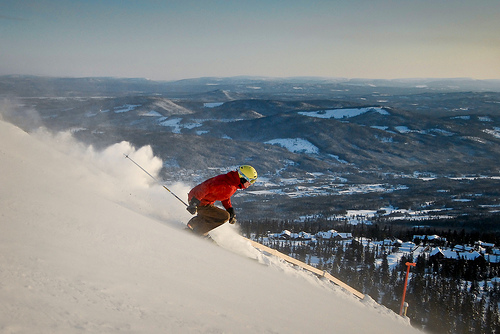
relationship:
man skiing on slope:
[189, 161, 257, 236] [17, 213, 417, 332]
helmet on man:
[237, 164, 259, 180] [181, 159, 257, 248]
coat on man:
[188, 170, 246, 206] [181, 159, 257, 248]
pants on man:
[189, 202, 230, 239] [185, 161, 259, 239]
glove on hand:
[182, 191, 199, 215] [187, 198, 196, 212]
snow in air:
[0, 114, 436, 330] [2, 3, 496, 85]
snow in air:
[297, 107, 390, 119] [2, 3, 496, 85]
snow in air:
[266, 134, 319, 155] [2, 3, 496, 85]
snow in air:
[327, 204, 458, 224] [2, 3, 496, 85]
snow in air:
[367, 122, 392, 131] [2, 3, 496, 85]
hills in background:
[0, 75, 497, 178] [5, 2, 494, 169]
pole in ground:
[393, 256, 418, 316] [0, 118, 425, 331]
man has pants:
[187, 165, 258, 238] [188, 204, 230, 235]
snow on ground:
[0, 121, 423, 334] [1, 79, 497, 331]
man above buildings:
[187, 165, 258, 238] [261, 216, 498, 278]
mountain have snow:
[0, 123, 416, 334] [180, 289, 319, 314]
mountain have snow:
[183, 89, 228, 110] [180, 289, 319, 314]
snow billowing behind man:
[0, 121, 423, 334] [187, 165, 258, 238]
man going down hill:
[187, 165, 258, 238] [1, 116, 422, 331]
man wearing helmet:
[187, 165, 258, 238] [233, 162, 260, 184]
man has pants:
[187, 165, 258, 238] [180, 197, 213, 237]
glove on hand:
[225, 206, 237, 223] [223, 202, 237, 222]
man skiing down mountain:
[187, 165, 258, 238] [0, 123, 416, 334]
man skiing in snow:
[187, 165, 258, 238] [0, 114, 436, 330]